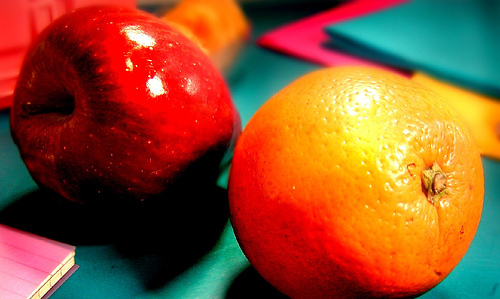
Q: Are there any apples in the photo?
A: Yes, there is an apple.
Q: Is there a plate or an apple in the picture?
A: Yes, there is an apple.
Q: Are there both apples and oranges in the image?
A: Yes, there are both an apple and oranges.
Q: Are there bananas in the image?
A: No, there are no bananas.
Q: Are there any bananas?
A: No, there are no bananas.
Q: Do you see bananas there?
A: No, there are no bananas.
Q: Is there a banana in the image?
A: No, there are no bananas.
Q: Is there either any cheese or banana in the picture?
A: No, there are no bananas or cheese.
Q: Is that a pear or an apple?
A: That is an apple.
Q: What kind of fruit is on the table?
A: The fruit is an apple.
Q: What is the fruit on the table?
A: The fruit is an apple.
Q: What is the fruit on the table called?
A: The fruit is an apple.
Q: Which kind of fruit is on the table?
A: The fruit is an apple.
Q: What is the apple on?
A: The apple is on the table.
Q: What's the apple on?
A: The apple is on the table.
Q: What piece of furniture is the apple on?
A: The apple is on the table.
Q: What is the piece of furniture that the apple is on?
A: The piece of furniture is a table.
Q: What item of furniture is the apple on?
A: The apple is on the table.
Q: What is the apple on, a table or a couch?
A: The apple is on a table.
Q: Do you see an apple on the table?
A: Yes, there is an apple on the table.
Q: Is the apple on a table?
A: Yes, the apple is on a table.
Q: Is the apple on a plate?
A: No, the apple is on a table.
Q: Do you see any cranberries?
A: No, there are no cranberries.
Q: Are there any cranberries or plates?
A: No, there are no cranberries or plates.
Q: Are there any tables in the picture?
A: Yes, there is a table.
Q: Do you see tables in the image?
A: Yes, there is a table.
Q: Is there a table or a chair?
A: Yes, there is a table.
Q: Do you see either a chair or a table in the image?
A: Yes, there is a table.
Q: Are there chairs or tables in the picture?
A: Yes, there is a table.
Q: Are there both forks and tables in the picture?
A: No, there is a table but no forks.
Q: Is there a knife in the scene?
A: No, there are no knives.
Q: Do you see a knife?
A: No, there are no knives.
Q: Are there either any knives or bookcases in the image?
A: No, there are no knives or bookcases.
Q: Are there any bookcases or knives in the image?
A: No, there are no knives or bookcases.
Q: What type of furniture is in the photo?
A: The furniture is a table.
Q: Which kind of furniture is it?
A: The piece of furniture is a table.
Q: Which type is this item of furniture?
A: This is a table.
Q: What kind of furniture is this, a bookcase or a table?
A: This is a table.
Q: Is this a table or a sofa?
A: This is a table.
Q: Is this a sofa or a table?
A: This is a table.